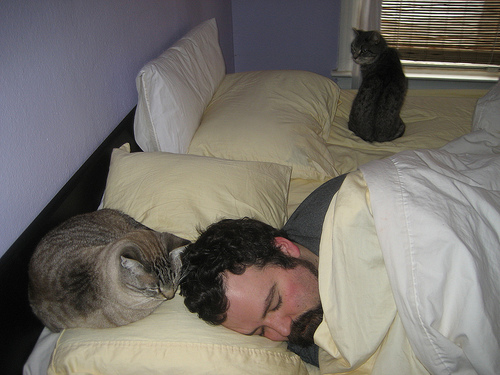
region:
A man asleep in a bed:
[176, 151, 498, 345]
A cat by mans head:
[23, 204, 302, 347]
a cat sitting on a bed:
[337, 24, 418, 148]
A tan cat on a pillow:
[37, 208, 189, 337]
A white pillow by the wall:
[124, 11, 245, 154]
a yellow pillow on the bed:
[198, 64, 344, 179]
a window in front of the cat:
[351, 6, 496, 76]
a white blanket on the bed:
[376, 126, 492, 337]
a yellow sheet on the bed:
[315, 187, 402, 357]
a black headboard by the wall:
[32, 94, 179, 221]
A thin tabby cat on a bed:
[346, 23, 407, 142]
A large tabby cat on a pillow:
[30, 206, 192, 332]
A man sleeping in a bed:
[179, 170, 352, 370]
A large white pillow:
[131, 17, 224, 152]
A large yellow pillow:
[46, 145, 293, 374]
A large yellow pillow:
[186, 70, 340, 180]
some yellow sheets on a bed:
[271, 88, 486, 217]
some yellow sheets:
[314, 169, 432, 374]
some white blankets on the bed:
[361, 88, 498, 370]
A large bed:
[16, 90, 496, 374]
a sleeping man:
[177, 130, 499, 372]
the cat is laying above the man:
[24, 203, 346, 358]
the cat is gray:
[24, 204, 189, 331]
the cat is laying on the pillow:
[22, 143, 292, 374]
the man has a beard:
[283, 255, 326, 352]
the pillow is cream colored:
[188, 59, 338, 180]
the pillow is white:
[131, 18, 228, 153]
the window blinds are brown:
[374, 0, 496, 73]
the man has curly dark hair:
[176, 213, 285, 330]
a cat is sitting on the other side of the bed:
[338, 23, 411, 144]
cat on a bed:
[17, 202, 186, 341]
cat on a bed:
[333, 23, 416, 149]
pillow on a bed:
[123, 14, 230, 164]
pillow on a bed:
[169, 58, 348, 193]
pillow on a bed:
[32, 138, 318, 373]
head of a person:
[162, 212, 324, 348]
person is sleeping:
[170, 165, 367, 362]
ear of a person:
[269, 230, 302, 262]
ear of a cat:
[112, 245, 146, 281]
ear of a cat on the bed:
[165, 230, 193, 262]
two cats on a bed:
[7, 11, 489, 338]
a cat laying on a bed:
[4, 93, 296, 374]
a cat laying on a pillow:
[32, 168, 217, 344]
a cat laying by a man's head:
[62, 176, 332, 372]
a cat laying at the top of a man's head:
[53, 143, 347, 373]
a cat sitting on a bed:
[282, 26, 445, 191]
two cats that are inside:
[110, 13, 483, 373]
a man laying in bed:
[150, 72, 495, 348]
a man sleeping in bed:
[169, 96, 474, 373]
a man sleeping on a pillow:
[104, 129, 389, 368]